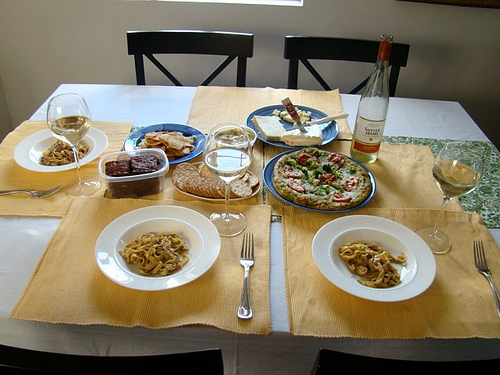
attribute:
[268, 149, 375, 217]
pizza — small, round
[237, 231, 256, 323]
fork — silver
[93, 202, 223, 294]
bowl — round, white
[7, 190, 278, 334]
placemat — yellow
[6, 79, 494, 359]
table cloth — white 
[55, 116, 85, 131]
wine — white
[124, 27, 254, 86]
chair — dark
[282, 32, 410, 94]
chair — dark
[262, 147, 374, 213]
plate — blue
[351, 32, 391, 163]
wine bottle — partially full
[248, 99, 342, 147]
plate — blue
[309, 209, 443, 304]
bowl — White 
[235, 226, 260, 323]
fork — shiny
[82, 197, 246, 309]
bowl — white 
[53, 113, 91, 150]
wine — white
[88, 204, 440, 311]
bowls — white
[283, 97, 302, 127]
handle — brown 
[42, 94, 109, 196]
wine glass — partially full